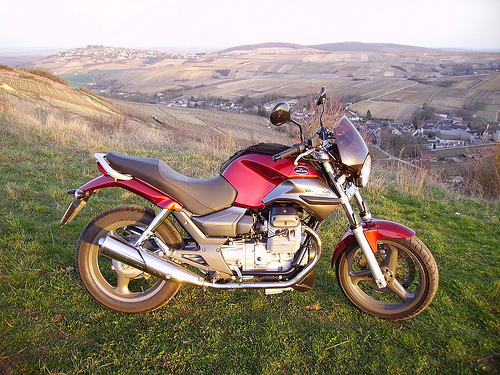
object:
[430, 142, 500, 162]
house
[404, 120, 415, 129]
house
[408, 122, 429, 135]
house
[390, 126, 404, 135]
house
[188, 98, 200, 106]
house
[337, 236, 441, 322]
tire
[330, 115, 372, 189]
farrings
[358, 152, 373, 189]
headlight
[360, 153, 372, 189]
light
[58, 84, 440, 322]
motorcycle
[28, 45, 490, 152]
land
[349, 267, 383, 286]
spokes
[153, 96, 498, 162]
countryside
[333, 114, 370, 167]
visor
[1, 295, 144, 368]
grass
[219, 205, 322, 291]
engine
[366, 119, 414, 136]
buildings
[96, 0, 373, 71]
sky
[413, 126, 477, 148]
house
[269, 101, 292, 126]
mirrors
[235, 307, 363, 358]
grass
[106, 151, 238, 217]
seat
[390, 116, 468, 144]
buildings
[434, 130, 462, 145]
house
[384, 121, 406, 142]
house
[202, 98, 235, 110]
house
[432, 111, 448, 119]
house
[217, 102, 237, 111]
house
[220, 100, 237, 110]
house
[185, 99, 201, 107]
house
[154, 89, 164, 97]
house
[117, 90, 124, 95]
house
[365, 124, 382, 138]
house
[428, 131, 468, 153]
house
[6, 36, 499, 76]
hill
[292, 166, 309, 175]
label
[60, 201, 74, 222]
plate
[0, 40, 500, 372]
valley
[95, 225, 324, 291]
exhaust pipe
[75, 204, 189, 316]
wheel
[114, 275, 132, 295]
spokes